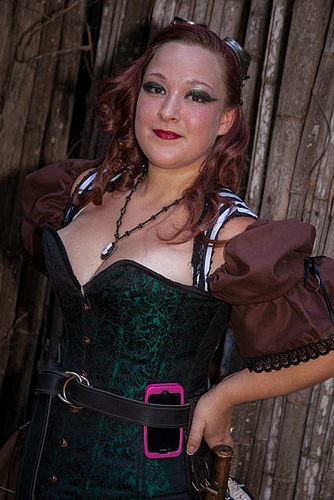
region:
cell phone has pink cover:
[142, 380, 183, 460]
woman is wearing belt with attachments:
[14, 363, 235, 498]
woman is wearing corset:
[29, 221, 240, 498]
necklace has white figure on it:
[100, 163, 184, 261]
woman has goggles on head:
[165, 13, 252, 86]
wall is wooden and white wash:
[0, 0, 333, 498]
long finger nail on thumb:
[184, 446, 194, 456]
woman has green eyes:
[141, 80, 215, 104]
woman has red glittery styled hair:
[71, 15, 251, 246]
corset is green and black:
[26, 221, 237, 497]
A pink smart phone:
[141, 378, 187, 462]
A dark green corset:
[9, 215, 233, 497]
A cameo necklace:
[98, 163, 206, 261]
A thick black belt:
[20, 354, 224, 496]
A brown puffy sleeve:
[199, 214, 330, 381]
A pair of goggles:
[156, 10, 256, 77]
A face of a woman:
[130, 17, 239, 177]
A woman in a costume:
[14, 12, 330, 496]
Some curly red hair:
[87, 16, 254, 249]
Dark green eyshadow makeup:
[181, 83, 221, 104]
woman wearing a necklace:
[110, 170, 143, 233]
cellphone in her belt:
[133, 379, 201, 461]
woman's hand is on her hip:
[173, 386, 240, 456]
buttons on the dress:
[77, 304, 96, 443]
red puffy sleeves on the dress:
[220, 223, 303, 304]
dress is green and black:
[117, 398, 129, 476]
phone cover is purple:
[130, 387, 196, 465]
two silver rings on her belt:
[67, 365, 88, 405]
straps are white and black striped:
[206, 189, 248, 235]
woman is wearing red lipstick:
[151, 119, 195, 143]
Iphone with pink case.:
[139, 382, 186, 462]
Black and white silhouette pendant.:
[95, 238, 122, 259]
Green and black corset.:
[38, 216, 235, 496]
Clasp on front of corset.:
[49, 293, 93, 486]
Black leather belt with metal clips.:
[17, 357, 219, 498]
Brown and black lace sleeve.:
[204, 215, 331, 372]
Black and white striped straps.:
[183, 182, 256, 292]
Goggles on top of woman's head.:
[167, 15, 252, 78]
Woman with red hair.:
[102, 10, 259, 191]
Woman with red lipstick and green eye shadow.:
[140, 66, 220, 147]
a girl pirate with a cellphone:
[13, 8, 326, 496]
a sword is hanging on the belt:
[183, 384, 232, 498]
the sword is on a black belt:
[15, 303, 105, 498]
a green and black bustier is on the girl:
[17, 224, 205, 493]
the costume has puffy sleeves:
[4, 161, 333, 369]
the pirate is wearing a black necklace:
[100, 164, 205, 264]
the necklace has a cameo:
[99, 229, 123, 262]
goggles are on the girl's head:
[151, 11, 252, 94]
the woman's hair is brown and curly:
[82, 24, 247, 255]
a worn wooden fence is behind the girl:
[15, 7, 331, 491]